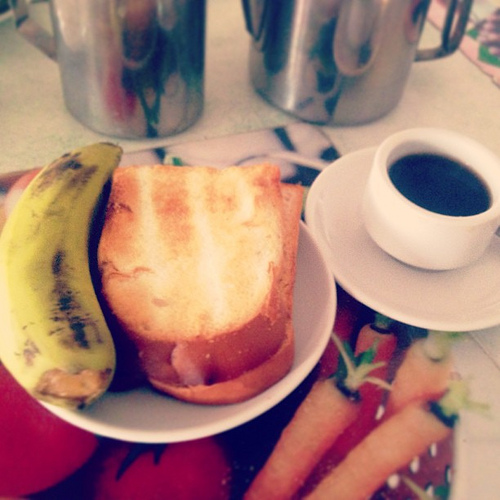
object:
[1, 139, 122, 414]
banana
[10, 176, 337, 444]
bowl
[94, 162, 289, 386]
toast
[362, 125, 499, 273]
cup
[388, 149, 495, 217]
coffee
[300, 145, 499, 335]
saucer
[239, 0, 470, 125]
pot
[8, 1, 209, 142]
pot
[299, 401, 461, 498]
carrot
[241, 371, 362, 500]
carrot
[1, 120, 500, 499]
mat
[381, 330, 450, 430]
carrot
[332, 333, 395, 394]
top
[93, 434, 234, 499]
tomato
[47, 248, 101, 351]
spot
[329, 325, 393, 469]
carrot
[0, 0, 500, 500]
table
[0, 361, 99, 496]
tomato